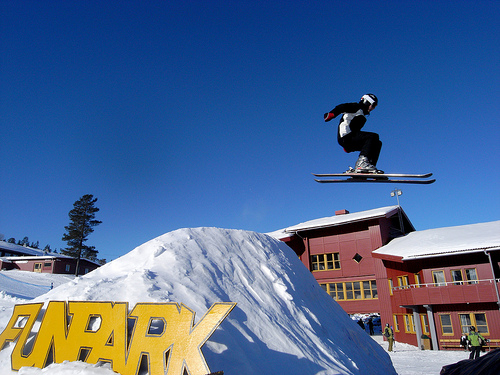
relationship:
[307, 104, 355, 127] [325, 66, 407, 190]
arms behind skier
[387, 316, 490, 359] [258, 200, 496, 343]
people beside building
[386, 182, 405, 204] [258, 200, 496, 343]
spotlight atop building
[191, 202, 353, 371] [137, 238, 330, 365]
shadow on snow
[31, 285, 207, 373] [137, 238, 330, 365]
sign in front of snow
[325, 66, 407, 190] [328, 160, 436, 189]
skier wears skis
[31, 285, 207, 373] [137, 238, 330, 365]
sign against snow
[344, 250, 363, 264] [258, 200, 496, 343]
window fronts building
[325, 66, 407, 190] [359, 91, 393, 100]
skier wears helmet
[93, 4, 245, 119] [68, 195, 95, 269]
sky above tree